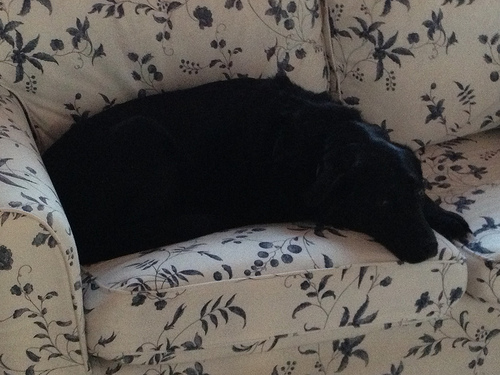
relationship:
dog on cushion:
[99, 92, 431, 237] [118, 224, 430, 370]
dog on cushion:
[43, 77, 471, 263] [126, 229, 387, 344]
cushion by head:
[355, 16, 491, 146] [292, 114, 494, 291]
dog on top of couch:
[43, 77, 471, 263] [16, 12, 491, 373]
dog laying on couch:
[43, 77, 471, 263] [16, 12, 491, 373]